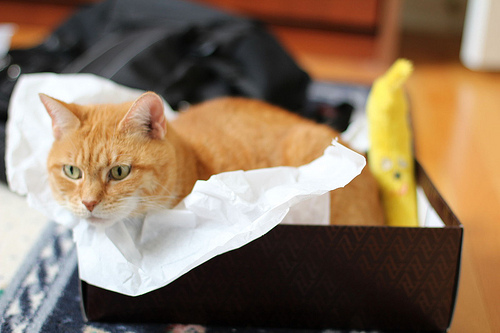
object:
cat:
[37, 89, 390, 226]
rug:
[0, 75, 83, 332]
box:
[81, 64, 466, 332]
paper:
[2, 70, 368, 300]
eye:
[56, 159, 84, 184]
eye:
[103, 160, 132, 182]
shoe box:
[69, 165, 461, 331]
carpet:
[0, 180, 88, 332]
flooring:
[415, 60, 498, 203]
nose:
[79, 193, 99, 210]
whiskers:
[36, 197, 156, 227]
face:
[371, 153, 416, 198]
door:
[451, 0, 499, 73]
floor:
[395, 20, 500, 329]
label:
[379, 153, 416, 200]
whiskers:
[135, 107, 153, 128]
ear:
[113, 89, 176, 139]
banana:
[365, 53, 420, 227]